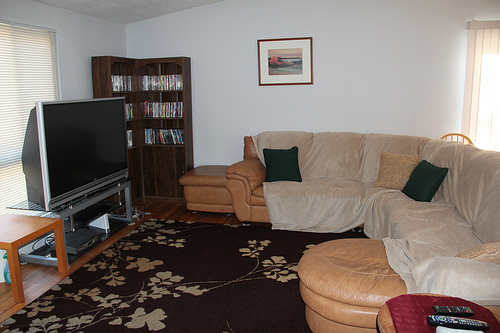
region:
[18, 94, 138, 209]
A large silver and grey television.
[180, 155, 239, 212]
A tan ottoman.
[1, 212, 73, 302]
A brown wooden end table.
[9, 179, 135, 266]
A grey entertainment stand.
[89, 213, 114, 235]
A white wii game console.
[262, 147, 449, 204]
Green throw pillows.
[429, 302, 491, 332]
Three remote controllers.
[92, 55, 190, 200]
Two wooden bookcases.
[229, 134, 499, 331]
A tan wraparound sofa.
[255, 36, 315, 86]
A brown framed picture.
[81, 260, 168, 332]
a floral pattern on a rug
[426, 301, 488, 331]
remotes on a table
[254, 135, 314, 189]
a black pillow on the sofa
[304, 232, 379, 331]
a tan ottoman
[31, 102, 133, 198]
a large flat screen tv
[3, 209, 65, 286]
a wooden side table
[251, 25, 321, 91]
a painting on the wall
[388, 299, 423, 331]
a burgundy place mat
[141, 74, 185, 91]
video tapes on a shelf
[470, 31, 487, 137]
sheer white curtains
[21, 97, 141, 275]
a TV in the living room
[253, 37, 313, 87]
a picture on the wall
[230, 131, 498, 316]
a large corner sofa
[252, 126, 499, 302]
a sheet on the sofa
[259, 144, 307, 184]
a green pillow on the sofa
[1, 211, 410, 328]
a brown rug on the floor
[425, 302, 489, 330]
remotes on a red cloth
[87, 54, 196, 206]
a shelf in the corner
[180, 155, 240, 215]
a footrest beside the sofa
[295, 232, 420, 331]
a footrest in front of the sofa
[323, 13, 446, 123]
white wall behind the couch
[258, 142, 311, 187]
a green pillow on edge of sofa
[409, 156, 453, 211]
green pillow on middle of sofa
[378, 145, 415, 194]
a beige pillow next to green pillow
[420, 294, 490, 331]
three remote controllers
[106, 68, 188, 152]
multiple books on a shelf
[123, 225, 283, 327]
brown carpet with plant design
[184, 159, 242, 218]
an auto man next to sofa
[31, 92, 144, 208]
a t.v. in front of sofa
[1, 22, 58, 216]
some white blinds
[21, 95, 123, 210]
A large television on a table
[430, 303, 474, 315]
A black remote control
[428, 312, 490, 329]
A black remote control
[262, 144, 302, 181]
A small black pillow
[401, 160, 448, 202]
A small black pillow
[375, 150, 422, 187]
A small brown pillow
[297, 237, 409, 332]
A large brown ottoman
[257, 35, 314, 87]
A picture on the wall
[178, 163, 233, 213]
A large brown ottoman